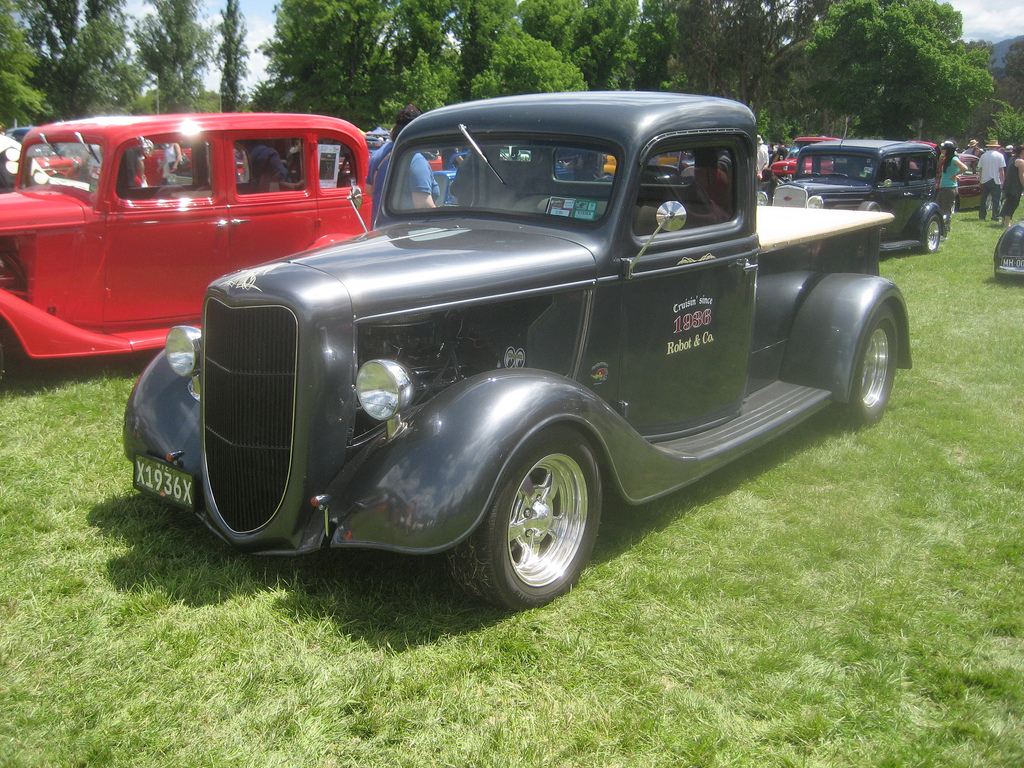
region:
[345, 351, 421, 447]
Headlight on a truck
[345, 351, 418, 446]
Headlight on a black truck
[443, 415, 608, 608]
Tire of a truck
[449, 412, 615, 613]
Tire of a black truck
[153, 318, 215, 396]
Headlight of a truck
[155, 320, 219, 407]
Headlight of a black truck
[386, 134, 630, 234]
Windshield of a truck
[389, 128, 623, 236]
Windshield of a black truck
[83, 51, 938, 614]
Car is parked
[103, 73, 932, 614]
Black car is parked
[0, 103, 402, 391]
Red car parked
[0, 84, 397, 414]
Red car is parked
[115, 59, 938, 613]
Car parked on the grass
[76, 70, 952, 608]
Black car parked on the grass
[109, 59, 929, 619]
Black car is parked on the grass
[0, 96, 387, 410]
Red car parked on the grass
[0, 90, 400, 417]
Red car is parked on the grass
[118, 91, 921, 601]
Antique black pick up truck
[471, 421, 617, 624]
Tire with shiny aluminum wheels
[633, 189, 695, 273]
Rear view mirror on black truck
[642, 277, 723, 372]
Logo on the door of truck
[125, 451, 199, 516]
License plate on black truck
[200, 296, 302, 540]
Grill on front of black truck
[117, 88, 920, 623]
vintage black truck parked on grass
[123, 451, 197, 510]
license plate of black vintage truck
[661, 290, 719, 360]
company logo on side of black truck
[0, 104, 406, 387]
red vintage truck next to black truck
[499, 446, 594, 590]
tire rim on black truck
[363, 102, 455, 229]
person in blue shirt between trucks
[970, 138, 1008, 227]
man with hat and white shirt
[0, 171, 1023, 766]
grass on ground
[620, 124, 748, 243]
open window of black truck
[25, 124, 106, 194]
windshield of red truck with wipers pointing up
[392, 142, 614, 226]
glass is clean and clear